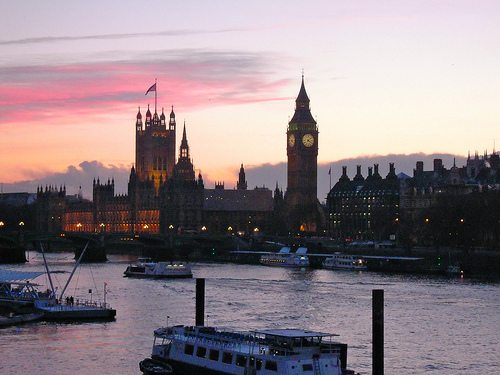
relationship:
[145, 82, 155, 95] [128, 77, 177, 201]
flag on top of building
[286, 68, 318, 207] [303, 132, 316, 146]
tower has clock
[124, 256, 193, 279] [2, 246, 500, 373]
boat on river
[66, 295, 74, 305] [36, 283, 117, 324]
people standing on boat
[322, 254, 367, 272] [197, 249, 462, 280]
boat at pier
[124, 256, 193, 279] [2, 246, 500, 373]
boat on top of river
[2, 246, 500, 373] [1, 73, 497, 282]
river in front of town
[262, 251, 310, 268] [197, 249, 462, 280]
boat docked at pier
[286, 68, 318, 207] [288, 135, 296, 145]
tower has clock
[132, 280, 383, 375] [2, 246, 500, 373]
boat on top of river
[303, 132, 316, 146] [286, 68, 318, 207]
clock on side of tower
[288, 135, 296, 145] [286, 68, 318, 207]
clock on side of tower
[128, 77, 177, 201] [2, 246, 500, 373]
building by river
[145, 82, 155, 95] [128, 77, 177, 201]
flag flying from building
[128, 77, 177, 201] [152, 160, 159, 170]
building has window